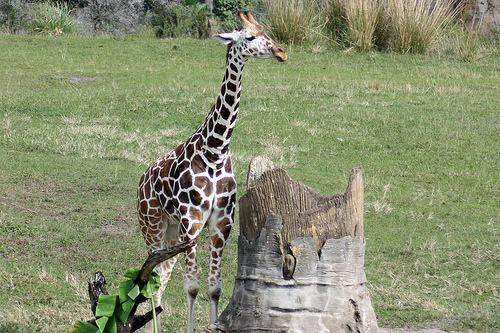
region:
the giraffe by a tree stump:
[86, 10, 438, 331]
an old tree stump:
[235, 157, 405, 324]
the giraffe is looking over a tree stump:
[162, 15, 317, 185]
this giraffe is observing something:
[80, 15, 300, 317]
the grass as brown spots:
[38, 55, 484, 150]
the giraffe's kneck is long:
[176, 12, 286, 139]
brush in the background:
[280, 5, 477, 75]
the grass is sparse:
[17, 45, 165, 320]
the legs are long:
[122, 126, 238, 322]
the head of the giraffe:
[194, 15, 308, 80]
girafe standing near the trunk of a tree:
[139, 11, 289, 331]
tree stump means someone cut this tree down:
[237, 143, 381, 331]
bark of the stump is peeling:
[247, 168, 359, 258]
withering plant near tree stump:
[66, 274, 162, 324]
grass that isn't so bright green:
[303, 55, 473, 159]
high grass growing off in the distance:
[276, 0, 451, 52]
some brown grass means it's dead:
[66, 112, 138, 167]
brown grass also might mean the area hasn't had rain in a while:
[81, 114, 145, 162]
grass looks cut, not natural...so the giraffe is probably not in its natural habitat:
[363, 45, 491, 173]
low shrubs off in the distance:
[53, 0, 210, 37]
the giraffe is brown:
[83, 5, 295, 309]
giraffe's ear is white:
[207, 20, 247, 62]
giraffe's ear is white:
[205, 26, 240, 48]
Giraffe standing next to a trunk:
[133, 8, 289, 332]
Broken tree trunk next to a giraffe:
[237, 151, 369, 332]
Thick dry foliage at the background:
[266, 2, 467, 56]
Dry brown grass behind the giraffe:
[49, 121, 186, 166]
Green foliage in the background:
[25, 0, 87, 36]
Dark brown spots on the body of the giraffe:
[159, 166, 203, 199]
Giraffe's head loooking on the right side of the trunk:
[210, 8, 292, 63]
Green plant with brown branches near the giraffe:
[61, 233, 204, 331]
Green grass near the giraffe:
[0, 213, 102, 255]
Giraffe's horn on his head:
[231, 6, 258, 29]